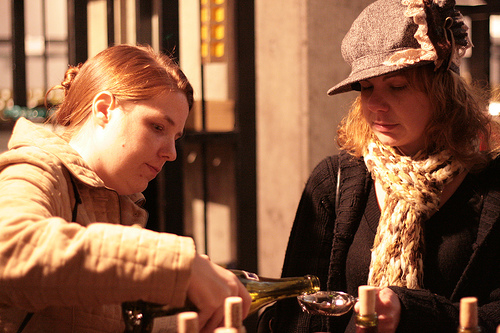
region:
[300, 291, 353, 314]
silver cup in hand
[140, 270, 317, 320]
green glass wine bottle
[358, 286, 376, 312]
tan cork in bottle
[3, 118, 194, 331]
brown quilted winter jacket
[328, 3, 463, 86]
brown tweed hat on head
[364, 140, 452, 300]
brown and tan scarf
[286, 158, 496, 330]
black cardigan sweater jacket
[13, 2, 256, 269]
black wood and glass doors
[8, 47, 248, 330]
woman pouring wine in cup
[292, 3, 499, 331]
woman holding silver cup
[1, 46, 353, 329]
A woman pouring a glass of wine.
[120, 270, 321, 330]
A green wine bottle.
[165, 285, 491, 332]
There are corks in the tops of the bottes.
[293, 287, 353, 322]
A glass being filled with wine.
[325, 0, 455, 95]
A woman wearing a brown hat.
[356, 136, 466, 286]
A woman wearing a scarf.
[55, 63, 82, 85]
There is a bun in the woman's hair.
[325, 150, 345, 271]
A black purse strap on the woman's shoulder.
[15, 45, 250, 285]
Windows on the building behind the woman.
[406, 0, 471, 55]
There is a lace decoration on the woman's hat.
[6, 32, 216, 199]
young woman with ginger colored hair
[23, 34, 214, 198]
young woman with red hair tied back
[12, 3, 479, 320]
Two young women in cold weather gear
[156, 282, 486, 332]
tops of bottles with corks showing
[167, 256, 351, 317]
liquid being poured from bottle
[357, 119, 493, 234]
knit scarf wrapped around kneck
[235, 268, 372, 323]
wine being poured into large metal spoon shaped container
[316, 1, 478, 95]
brown hat with large brim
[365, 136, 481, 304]
loosely knit muted tone scarf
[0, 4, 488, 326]
two warmly dressed young women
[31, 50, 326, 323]
woman pouring a bottle of wine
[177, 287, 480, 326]
four wine corks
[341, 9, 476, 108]
woman wearing a grey hat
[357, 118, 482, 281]
winter scarf around woman's neck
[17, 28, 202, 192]
woman with red hair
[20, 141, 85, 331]
black strap of purse around woman's shoulder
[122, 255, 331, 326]
green bottle of white wine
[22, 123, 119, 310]
woman wearing a tan quilted jacket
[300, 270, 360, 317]
small silver bowl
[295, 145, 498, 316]
woman wearing two black sweaters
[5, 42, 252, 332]
woman pouring bottle of liquid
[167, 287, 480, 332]
corks of other bottles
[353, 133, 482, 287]
scarf around woman's neck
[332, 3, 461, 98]
tweed hat of woman wearing scarf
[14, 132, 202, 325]
light brown coat of woman pouring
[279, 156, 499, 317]
black sweater of woman wearing scarf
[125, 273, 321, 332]
bottle being held and poured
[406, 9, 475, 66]
decoration on woman's tweed hat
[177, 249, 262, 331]
woman's hand holding bottle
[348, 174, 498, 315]
black shirt of woman wearing hat